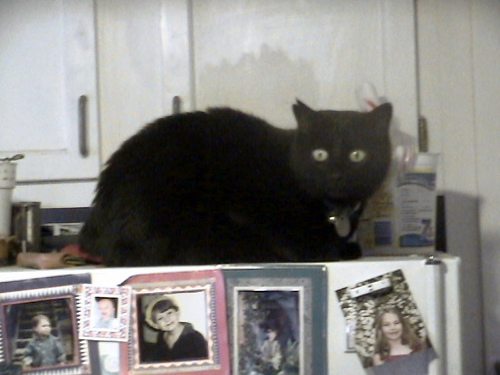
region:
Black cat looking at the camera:
[75, 94, 395, 258]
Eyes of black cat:
[307, 143, 372, 167]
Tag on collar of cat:
[328, 206, 355, 239]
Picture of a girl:
[336, 265, 438, 371]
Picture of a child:
[134, 292, 210, 362]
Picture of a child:
[3, 292, 77, 372]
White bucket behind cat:
[353, 152, 440, 254]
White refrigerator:
[0, 257, 461, 374]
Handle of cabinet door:
[74, 92, 93, 159]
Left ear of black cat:
[363, 102, 392, 139]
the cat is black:
[62, 77, 388, 255]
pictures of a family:
[3, 268, 470, 373]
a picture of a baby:
[6, 290, 73, 368]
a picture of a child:
[118, 288, 211, 365]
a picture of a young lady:
[333, 260, 441, 373]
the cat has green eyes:
[298, 115, 373, 175]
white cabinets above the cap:
[23, 4, 468, 189]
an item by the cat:
[371, 139, 447, 261]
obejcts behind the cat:
[3, 147, 70, 260]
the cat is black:
[64, 98, 390, 268]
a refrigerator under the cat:
[5, 246, 469, 368]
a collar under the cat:
[321, 193, 366, 245]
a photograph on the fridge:
[326, 263, 436, 370]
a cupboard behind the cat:
[0, 1, 107, 185]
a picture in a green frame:
[215, 261, 337, 373]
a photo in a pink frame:
[120, 267, 230, 374]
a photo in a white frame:
[69, 281, 134, 348]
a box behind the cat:
[350, 139, 445, 255]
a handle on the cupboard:
[74, 88, 94, 161]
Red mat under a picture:
[118, 270, 229, 373]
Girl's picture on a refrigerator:
[332, 268, 434, 370]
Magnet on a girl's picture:
[342, 275, 391, 295]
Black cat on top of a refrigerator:
[67, 95, 393, 259]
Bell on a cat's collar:
[325, 211, 337, 222]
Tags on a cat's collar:
[333, 209, 352, 239]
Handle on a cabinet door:
[73, 95, 93, 157]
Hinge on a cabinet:
[416, 115, 429, 160]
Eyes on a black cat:
[308, 147, 365, 161]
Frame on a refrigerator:
[217, 263, 327, 373]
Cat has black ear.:
[288, 99, 315, 126]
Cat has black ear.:
[368, 97, 405, 117]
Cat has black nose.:
[326, 165, 351, 188]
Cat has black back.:
[150, 100, 232, 130]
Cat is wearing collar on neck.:
[323, 191, 375, 233]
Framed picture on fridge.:
[16, 287, 96, 366]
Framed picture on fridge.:
[226, 287, 310, 367]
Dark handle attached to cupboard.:
[60, 95, 100, 155]